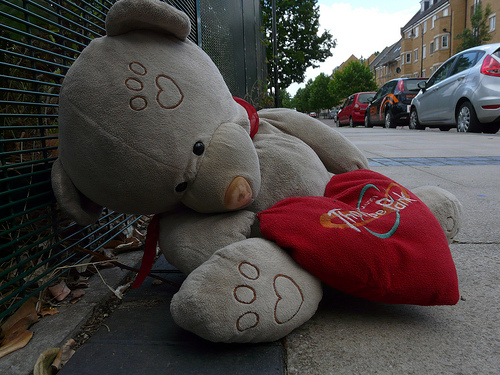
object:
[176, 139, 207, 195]
black eyes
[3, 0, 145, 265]
door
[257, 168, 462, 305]
heart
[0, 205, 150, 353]
debris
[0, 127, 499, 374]
sidewalk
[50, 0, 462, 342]
bear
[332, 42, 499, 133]
cars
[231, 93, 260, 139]
ribbon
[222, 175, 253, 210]
nose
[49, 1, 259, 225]
head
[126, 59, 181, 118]
paw print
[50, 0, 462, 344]
teddy bear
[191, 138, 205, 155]
eye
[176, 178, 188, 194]
eye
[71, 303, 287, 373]
asphalt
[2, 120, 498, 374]
ground